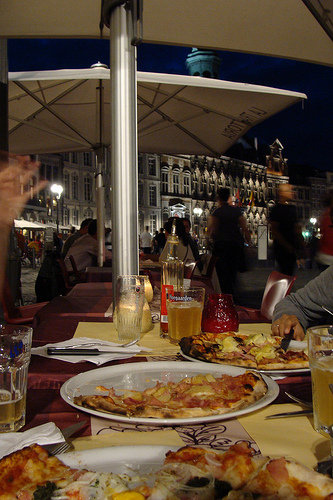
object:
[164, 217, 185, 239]
head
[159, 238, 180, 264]
arms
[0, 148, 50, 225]
hand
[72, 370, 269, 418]
pizza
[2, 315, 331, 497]
table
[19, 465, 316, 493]
cheese pizza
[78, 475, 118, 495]
cheese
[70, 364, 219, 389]
plate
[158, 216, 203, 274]
people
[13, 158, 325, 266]
background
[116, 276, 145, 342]
glass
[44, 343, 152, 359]
knife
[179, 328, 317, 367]
almost whole pizza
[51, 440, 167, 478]
piece gone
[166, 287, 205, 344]
beer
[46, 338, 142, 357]
fork and knife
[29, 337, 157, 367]
napkin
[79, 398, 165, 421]
crust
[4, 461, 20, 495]
tomato sauce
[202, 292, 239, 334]
candle holder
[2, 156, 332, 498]
restaurant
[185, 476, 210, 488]
onions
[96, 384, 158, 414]
pieces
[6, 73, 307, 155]
umbrella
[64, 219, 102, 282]
diners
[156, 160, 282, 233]
building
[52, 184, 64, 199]
streetlight